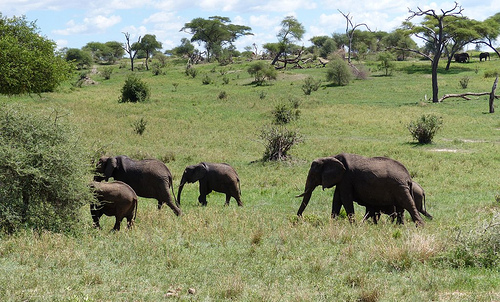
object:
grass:
[3, 59, 499, 300]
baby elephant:
[175, 163, 244, 205]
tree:
[401, 6, 467, 105]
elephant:
[297, 153, 422, 227]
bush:
[1, 105, 86, 239]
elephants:
[83, 183, 139, 230]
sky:
[0, 0, 500, 50]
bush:
[0, 14, 61, 93]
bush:
[260, 127, 296, 162]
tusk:
[296, 181, 320, 199]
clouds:
[1, 1, 311, 13]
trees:
[399, 16, 482, 72]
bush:
[119, 73, 150, 104]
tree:
[181, 16, 253, 67]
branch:
[440, 91, 499, 104]